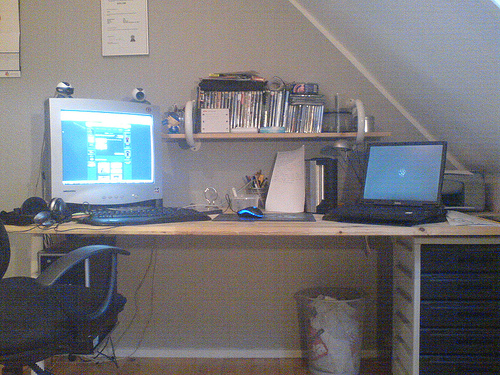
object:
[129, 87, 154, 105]
web cams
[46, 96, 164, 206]
monitor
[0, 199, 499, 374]
desk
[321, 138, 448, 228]
laptop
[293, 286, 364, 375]
can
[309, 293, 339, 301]
trash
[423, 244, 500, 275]
drawers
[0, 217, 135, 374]
chair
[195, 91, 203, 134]
games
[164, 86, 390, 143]
shelf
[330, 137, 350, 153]
lamp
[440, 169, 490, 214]
printer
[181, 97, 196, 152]
bracket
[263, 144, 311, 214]
paper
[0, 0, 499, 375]
space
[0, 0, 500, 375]
office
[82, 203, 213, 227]
keyboard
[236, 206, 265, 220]
mouse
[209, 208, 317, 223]
pad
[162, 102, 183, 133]
figurine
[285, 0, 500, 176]
roof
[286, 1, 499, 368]
right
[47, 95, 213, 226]
pc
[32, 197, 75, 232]
headphones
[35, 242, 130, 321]
arm